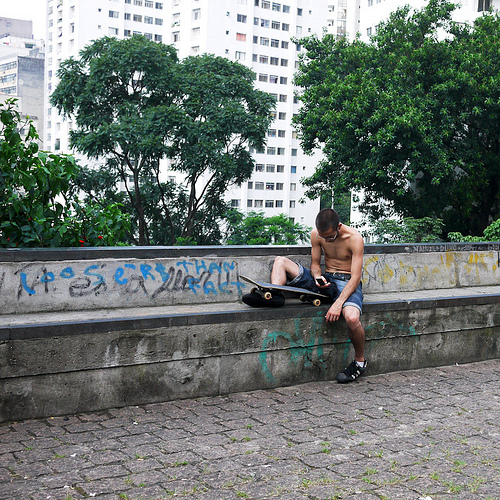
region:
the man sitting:
[241, 204, 370, 389]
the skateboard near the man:
[237, 272, 330, 306]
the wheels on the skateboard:
[248, 289, 320, 309]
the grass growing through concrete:
[53, 400, 496, 498]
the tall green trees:
[2, 20, 497, 238]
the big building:
[0, 2, 496, 232]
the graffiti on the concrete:
[7, 248, 497, 306]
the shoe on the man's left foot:
[335, 360, 368, 385]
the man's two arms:
[308, 225, 360, 320]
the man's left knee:
[343, 310, 363, 330]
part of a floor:
[310, 437, 325, 454]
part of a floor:
[289, 381, 336, 442]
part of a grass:
[308, 473, 329, 490]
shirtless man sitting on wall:
[268, 193, 371, 356]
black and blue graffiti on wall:
[9, 267, 42, 305]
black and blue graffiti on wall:
[223, 326, 305, 378]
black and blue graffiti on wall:
[379, 316, 437, 377]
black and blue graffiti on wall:
[406, 302, 472, 360]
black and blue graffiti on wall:
[52, 267, 120, 309]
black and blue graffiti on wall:
[114, 254, 156, 298]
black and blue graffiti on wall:
[154, 262, 192, 311]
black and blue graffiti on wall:
[176, 248, 225, 309]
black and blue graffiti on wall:
[169, 332, 237, 360]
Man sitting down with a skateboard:
[224, 196, 416, 391]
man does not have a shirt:
[302, 217, 369, 296]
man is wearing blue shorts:
[292, 266, 377, 313]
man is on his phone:
[290, 212, 372, 305]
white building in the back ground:
[240, 97, 319, 218]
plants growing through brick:
[135, 404, 499, 498]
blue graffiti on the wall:
[14, 256, 248, 309]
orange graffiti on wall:
[371, 246, 498, 283]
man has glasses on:
[310, 208, 348, 248]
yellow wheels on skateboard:
[242, 272, 335, 312]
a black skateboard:
[240, 272, 326, 304]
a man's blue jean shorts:
[285, 256, 366, 313]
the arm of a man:
[338, 231, 367, 297]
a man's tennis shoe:
[336, 358, 372, 382]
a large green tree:
[53, 34, 288, 251]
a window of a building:
[257, 54, 269, 64]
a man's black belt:
[324, 270, 352, 280]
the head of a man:
[310, 208, 345, 243]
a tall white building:
[167, 2, 327, 229]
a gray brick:
[305, 438, 359, 469]